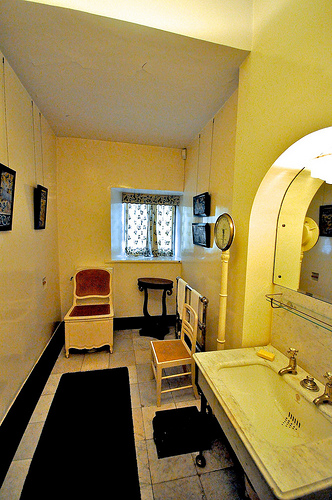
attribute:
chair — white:
[143, 298, 204, 403]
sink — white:
[178, 341, 331, 493]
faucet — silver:
[276, 341, 328, 420]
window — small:
[107, 182, 184, 264]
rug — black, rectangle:
[28, 365, 138, 498]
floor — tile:
[0, 299, 197, 499]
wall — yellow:
[224, 78, 328, 395]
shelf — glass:
[266, 295, 330, 341]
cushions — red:
[76, 265, 107, 321]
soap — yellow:
[250, 350, 282, 366]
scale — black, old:
[150, 400, 209, 448]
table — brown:
[130, 269, 170, 340]